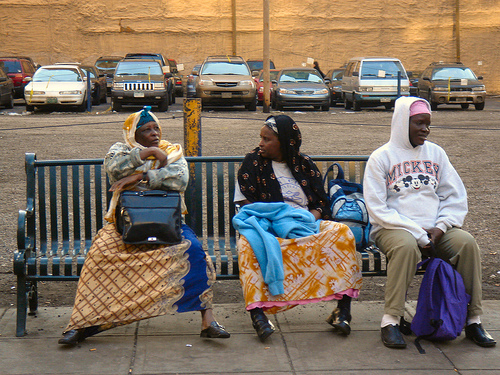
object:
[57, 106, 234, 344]
women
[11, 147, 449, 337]
bench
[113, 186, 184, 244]
bag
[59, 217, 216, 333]
skirts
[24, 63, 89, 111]
cars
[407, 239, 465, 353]
backpack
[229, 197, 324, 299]
sweater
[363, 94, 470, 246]
hoodie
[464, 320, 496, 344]
shoes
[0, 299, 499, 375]
sidewalk